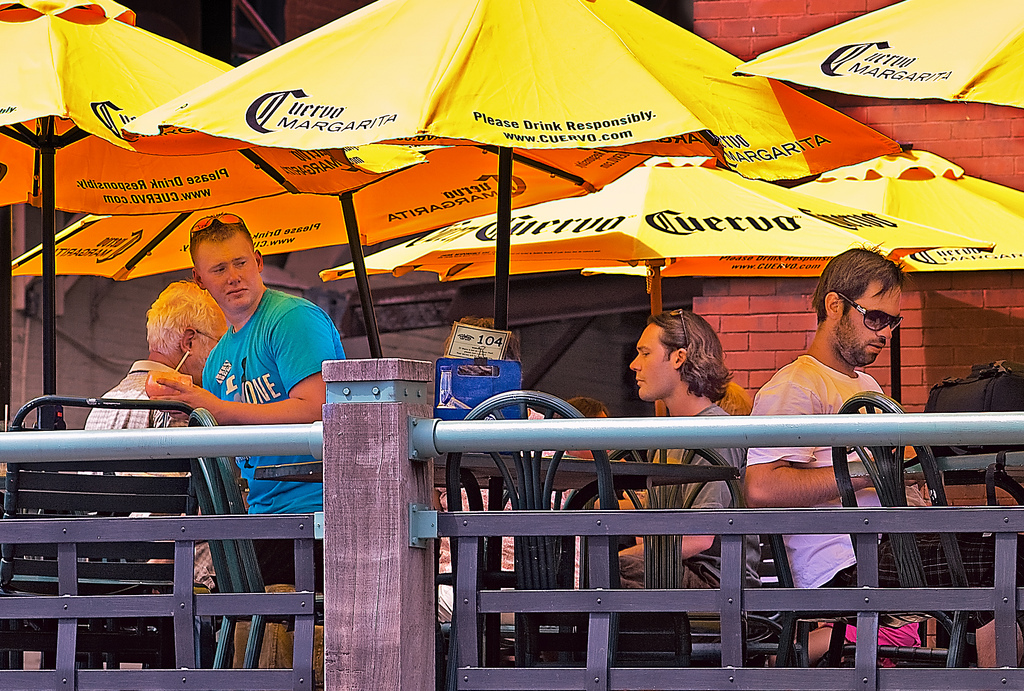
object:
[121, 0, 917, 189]
umbrellas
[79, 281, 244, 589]
man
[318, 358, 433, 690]
wood post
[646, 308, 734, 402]
hair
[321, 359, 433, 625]
post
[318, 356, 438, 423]
metal pieces